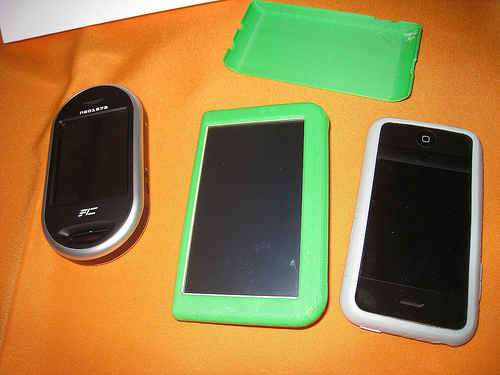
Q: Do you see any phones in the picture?
A: Yes, there is a phone.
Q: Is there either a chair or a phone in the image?
A: Yes, there is a phone.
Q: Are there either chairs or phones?
A: Yes, there is a phone.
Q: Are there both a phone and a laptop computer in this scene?
A: No, there is a phone but no laptops.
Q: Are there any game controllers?
A: No, there are no game controllers.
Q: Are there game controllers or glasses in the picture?
A: No, there are no game controllers or glasses.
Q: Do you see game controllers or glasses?
A: No, there are no game controllers or glasses.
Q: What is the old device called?
A: The device is a phone.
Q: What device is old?
A: The device is a phone.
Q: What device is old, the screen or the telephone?
A: The telephone is old.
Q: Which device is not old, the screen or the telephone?
A: The screen is not old.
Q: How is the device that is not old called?
A: The device is a screen.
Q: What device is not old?
A: The device is a screen.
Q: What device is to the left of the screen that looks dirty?
A: The device is a phone.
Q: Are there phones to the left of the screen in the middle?
A: Yes, there is a phone to the left of the screen.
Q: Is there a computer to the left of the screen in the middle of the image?
A: No, there is a phone to the left of the screen.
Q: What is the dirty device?
A: The device is a screen.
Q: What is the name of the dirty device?
A: The device is a screen.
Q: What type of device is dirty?
A: The device is a screen.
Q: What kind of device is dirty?
A: The device is a screen.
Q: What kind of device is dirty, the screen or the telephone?
A: The screen is dirty.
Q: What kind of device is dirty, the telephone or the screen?
A: The screen is dirty.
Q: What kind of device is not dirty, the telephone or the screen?
A: The telephone is not dirty.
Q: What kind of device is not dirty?
A: The device is a phone.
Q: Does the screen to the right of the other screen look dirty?
A: Yes, the screen is dirty.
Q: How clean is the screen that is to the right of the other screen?
A: The screen is dirty.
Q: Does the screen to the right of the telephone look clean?
A: No, the screen is dirty.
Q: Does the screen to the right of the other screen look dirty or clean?
A: The screen is dirty.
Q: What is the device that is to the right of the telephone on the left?
A: The device is a screen.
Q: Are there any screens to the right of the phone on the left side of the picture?
A: Yes, there is a screen to the right of the telephone.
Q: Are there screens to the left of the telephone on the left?
A: No, the screen is to the right of the phone.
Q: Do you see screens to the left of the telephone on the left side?
A: No, the screen is to the right of the phone.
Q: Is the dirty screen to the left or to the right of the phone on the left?
A: The screen is to the right of the phone.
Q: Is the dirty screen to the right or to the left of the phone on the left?
A: The screen is to the right of the phone.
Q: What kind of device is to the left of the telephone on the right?
A: The device is a screen.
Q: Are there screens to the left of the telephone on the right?
A: Yes, there is a screen to the left of the telephone.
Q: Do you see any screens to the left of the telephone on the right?
A: Yes, there is a screen to the left of the telephone.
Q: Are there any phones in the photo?
A: Yes, there is a phone.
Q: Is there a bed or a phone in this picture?
A: Yes, there is a phone.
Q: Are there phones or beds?
A: Yes, there is a phone.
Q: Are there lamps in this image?
A: No, there are no lamps.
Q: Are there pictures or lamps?
A: No, there are no lamps or pictures.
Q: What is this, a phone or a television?
A: This is a phone.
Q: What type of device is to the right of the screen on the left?
A: The device is a phone.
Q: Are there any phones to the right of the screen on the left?
A: Yes, there is a phone to the right of the screen.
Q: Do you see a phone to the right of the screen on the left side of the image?
A: Yes, there is a phone to the right of the screen.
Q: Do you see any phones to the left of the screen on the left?
A: No, the phone is to the right of the screen.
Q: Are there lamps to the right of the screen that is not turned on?
A: No, there is a phone to the right of the screen.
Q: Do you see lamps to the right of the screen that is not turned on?
A: No, there is a phone to the right of the screen.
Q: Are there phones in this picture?
A: Yes, there is a phone.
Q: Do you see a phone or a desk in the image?
A: Yes, there is a phone.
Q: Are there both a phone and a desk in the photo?
A: No, there is a phone but no desks.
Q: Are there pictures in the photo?
A: No, there are no pictures.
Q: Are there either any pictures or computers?
A: No, there are no pictures or computers.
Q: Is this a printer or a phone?
A: This is a phone.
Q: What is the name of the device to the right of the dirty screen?
A: The device is a phone.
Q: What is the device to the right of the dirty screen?
A: The device is a phone.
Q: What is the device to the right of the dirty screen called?
A: The device is a phone.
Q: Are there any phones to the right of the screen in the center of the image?
A: Yes, there is a phone to the right of the screen.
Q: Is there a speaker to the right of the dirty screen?
A: No, there is a phone to the right of the screen.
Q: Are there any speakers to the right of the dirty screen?
A: No, there is a phone to the right of the screen.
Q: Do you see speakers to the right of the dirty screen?
A: No, there is a phone to the right of the screen.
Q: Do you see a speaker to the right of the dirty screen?
A: No, there is a phone to the right of the screen.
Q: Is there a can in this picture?
A: No, there are no cans.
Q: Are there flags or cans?
A: No, there are no cans or flags.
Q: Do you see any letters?
A: Yes, there are letters.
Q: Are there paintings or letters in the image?
A: Yes, there are letters.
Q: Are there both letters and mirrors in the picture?
A: No, there are letters but no mirrors.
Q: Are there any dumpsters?
A: No, there are no dumpsters.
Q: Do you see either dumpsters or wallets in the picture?
A: No, there are no dumpsters or wallets.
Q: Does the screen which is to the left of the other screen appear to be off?
A: Yes, the screen is off.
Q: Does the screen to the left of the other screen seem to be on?
A: No, the screen is off.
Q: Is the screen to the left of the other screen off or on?
A: The screen is off.